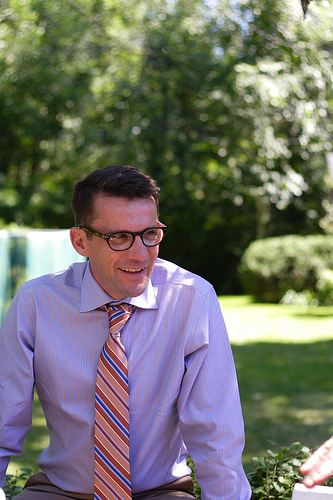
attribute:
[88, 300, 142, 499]
tie — knotted, striped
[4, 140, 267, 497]
man — sitting down, smiling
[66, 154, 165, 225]
hair — parted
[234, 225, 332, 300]
bushes — trimmed, blurry, distant, blurred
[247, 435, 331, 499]
plant — green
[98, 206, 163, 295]
face — smiling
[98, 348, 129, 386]
stripe — blue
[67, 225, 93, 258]
ear — large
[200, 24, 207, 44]
leaf — green